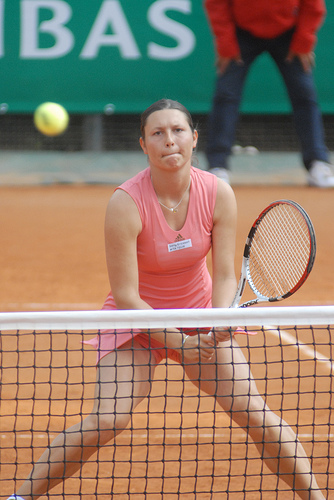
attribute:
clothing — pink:
[95, 164, 218, 361]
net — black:
[0, 305, 333, 499]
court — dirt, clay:
[2, 179, 333, 305]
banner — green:
[2, 0, 333, 112]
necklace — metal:
[150, 171, 192, 214]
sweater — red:
[205, 0, 324, 58]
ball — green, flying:
[34, 100, 70, 137]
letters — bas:
[16, 0, 199, 60]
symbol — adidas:
[173, 231, 186, 241]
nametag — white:
[165, 237, 195, 253]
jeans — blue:
[205, 24, 333, 165]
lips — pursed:
[160, 150, 183, 160]